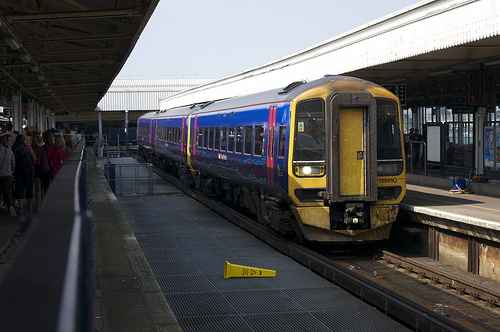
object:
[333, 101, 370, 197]
door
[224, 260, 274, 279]
cone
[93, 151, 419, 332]
ground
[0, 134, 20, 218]
people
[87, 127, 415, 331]
platform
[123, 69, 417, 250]
train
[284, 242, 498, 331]
tracks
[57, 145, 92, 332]
white sign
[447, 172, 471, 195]
item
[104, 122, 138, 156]
gate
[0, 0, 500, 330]
photo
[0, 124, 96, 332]
railing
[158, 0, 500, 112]
awning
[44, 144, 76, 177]
jacket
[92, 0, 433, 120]
sky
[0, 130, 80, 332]
pavement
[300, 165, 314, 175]
headlight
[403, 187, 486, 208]
shadow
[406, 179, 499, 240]
ground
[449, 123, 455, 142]
windows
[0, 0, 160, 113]
roof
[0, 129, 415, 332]
train station